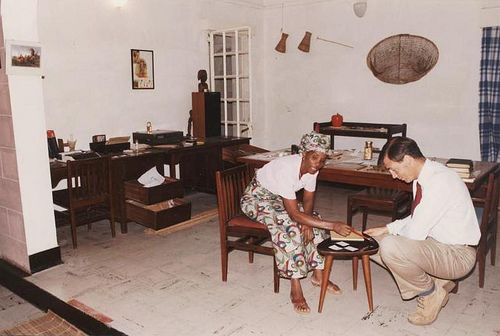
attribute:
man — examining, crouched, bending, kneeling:
[363, 138, 481, 326]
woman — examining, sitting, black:
[241, 133, 342, 314]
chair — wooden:
[212, 162, 283, 294]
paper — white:
[136, 165, 167, 188]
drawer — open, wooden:
[122, 168, 183, 205]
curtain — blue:
[478, 26, 499, 165]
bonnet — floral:
[297, 133, 332, 155]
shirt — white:
[254, 154, 319, 199]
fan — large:
[367, 34, 440, 87]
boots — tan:
[408, 279, 458, 326]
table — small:
[313, 232, 386, 311]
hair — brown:
[378, 134, 425, 171]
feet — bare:
[286, 274, 340, 313]